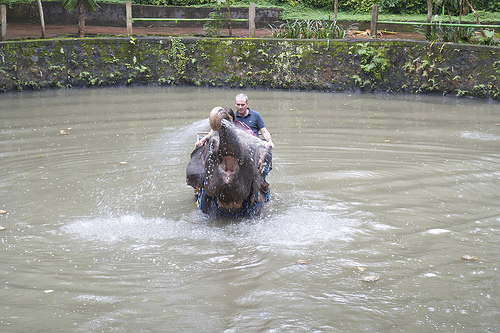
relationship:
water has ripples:
[1, 89, 498, 332] [304, 282, 351, 304]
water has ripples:
[1, 89, 498, 332] [192, 243, 231, 273]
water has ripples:
[1, 89, 498, 332] [275, 241, 300, 266]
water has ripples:
[1, 89, 498, 332] [324, 217, 371, 245]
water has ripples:
[1, 89, 498, 332] [2, 277, 97, 302]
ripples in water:
[232, 294, 286, 323] [318, 80, 478, 122]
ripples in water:
[304, 282, 351, 304] [1, 89, 498, 332]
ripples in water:
[340, 294, 379, 316] [1, 89, 498, 332]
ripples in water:
[422, 258, 444, 281] [1, 89, 498, 332]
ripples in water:
[211, 264, 271, 275] [1, 89, 498, 332]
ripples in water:
[471, 219, 498, 241] [1, 89, 498, 332]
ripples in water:
[68, 276, 133, 303] [1, 89, 498, 332]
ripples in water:
[393, 206, 456, 246] [342, 123, 475, 279]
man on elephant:
[232, 93, 275, 152] [185, 105, 271, 218]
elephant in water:
[185, 105, 271, 218] [1, 89, 498, 332]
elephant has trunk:
[185, 105, 271, 221] [202, 99, 236, 137]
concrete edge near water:
[4, 24, 489, 94] [1, 89, 498, 332]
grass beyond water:
[309, 3, 489, 44] [314, 110, 466, 242]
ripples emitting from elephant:
[8, 113, 497, 199] [182, 128, 272, 221]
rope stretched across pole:
[133, 14, 249, 22] [123, 0, 135, 36]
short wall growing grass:
[0, 35, 500, 97] [111, 35, 228, 75]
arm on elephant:
[258, 119, 283, 154] [185, 105, 271, 218]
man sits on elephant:
[232, 93, 275, 152] [199, 123, 265, 208]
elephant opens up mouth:
[185, 105, 271, 218] [215, 152, 240, 177]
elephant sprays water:
[185, 105, 271, 218] [1, 89, 498, 332]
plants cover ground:
[71, 41, 226, 79] [379, 128, 442, 181]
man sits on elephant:
[232, 93, 275, 152] [184, 102, 276, 221]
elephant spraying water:
[185, 105, 271, 221] [1, 89, 498, 332]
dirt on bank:
[2, 40, 499, 98] [5, 35, 499, 102]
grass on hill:
[280, 4, 498, 25] [1, 28, 498, 99]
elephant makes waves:
[185, 105, 271, 221] [134, 189, 334, 281]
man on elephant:
[232, 93, 275, 152] [185, 119, 282, 227]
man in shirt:
[232, 93, 275, 152] [228, 115, 255, 133]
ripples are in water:
[304, 282, 351, 304] [1, 89, 498, 332]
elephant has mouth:
[185, 105, 271, 221] [215, 141, 247, 188]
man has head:
[227, 96, 264, 125] [231, 92, 255, 117]